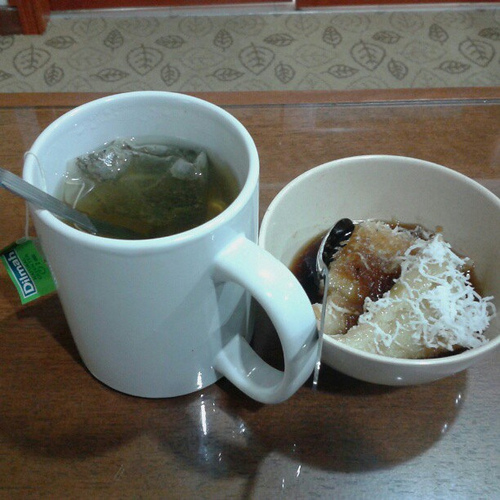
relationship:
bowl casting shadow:
[258, 147, 498, 379] [0, 383, 473, 481]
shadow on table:
[0, 383, 473, 481] [0, 2, 498, 499]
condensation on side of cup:
[40, 101, 250, 178] [22, 90, 319, 403]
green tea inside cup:
[53, 137, 239, 241] [22, 90, 319, 403]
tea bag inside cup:
[69, 137, 209, 232] [22, 87, 319, 404]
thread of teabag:
[12, 152, 47, 242] [54, 144, 204, 242]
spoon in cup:
[0, 167, 97, 232] [4, 80, 331, 405]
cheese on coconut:
[411, 249, 486, 349] [330, 232, 496, 360]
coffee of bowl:
[295, 252, 326, 294] [373, 354, 420, 397]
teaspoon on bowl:
[295, 232, 355, 385] [258, 147, 498, 379]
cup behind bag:
[22, 87, 319, 404] [9, 227, 56, 299]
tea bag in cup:
[69, 137, 209, 232] [4, 80, 331, 405]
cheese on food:
[411, 249, 486, 349] [290, 219, 495, 350]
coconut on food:
[366, 227, 496, 363] [298, 208, 498, 365]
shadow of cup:
[0, 383, 473, 481] [22, 87, 319, 404]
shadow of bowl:
[0, 383, 473, 481] [258, 147, 498, 379]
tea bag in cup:
[69, 137, 209, 232] [11, 100, 334, 412]